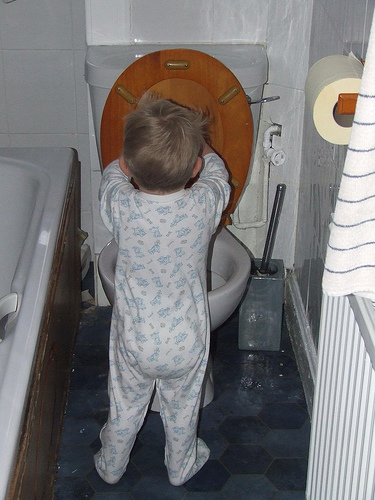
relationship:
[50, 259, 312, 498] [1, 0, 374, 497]
floor in bathroom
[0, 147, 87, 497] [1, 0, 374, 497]
bath tub in bathroom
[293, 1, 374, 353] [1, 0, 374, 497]
wall in bathroom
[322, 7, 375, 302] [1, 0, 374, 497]
cloth in bathroom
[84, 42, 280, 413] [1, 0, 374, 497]
toilet in bathroom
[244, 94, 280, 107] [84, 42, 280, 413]
handle on toilet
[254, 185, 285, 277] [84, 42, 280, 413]
toilet brush next to toilet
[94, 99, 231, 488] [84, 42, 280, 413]
baby in front of toilet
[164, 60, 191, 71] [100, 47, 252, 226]
rubber foot on toilet seat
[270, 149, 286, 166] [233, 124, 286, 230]
knob on pipe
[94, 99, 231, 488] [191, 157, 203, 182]
baby has an ear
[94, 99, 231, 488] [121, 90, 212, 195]
baby has hair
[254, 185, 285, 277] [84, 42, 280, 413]
toilet brush near toilet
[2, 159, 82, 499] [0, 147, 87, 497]
wood on bath tub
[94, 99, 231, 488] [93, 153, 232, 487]
baby in pajamas